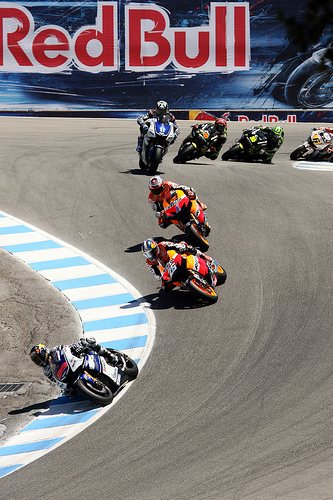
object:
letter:
[0, 1, 250, 71]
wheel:
[146, 146, 163, 173]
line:
[27, 255, 92, 273]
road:
[0, 122, 333, 498]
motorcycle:
[161, 186, 212, 254]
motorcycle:
[136, 113, 179, 176]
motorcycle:
[290, 126, 333, 162]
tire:
[185, 224, 210, 253]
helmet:
[148, 171, 164, 197]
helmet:
[155, 100, 167, 115]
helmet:
[272, 124, 285, 139]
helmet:
[215, 118, 227, 133]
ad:
[0, 0, 333, 122]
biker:
[145, 174, 208, 229]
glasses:
[212, 122, 224, 129]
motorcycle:
[52, 337, 138, 407]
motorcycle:
[157, 240, 229, 306]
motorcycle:
[173, 124, 219, 165]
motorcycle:
[221, 127, 271, 168]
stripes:
[0, 210, 157, 482]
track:
[0, 121, 333, 500]